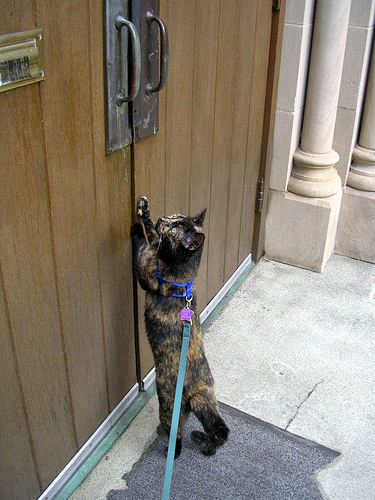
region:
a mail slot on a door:
[0, 24, 47, 99]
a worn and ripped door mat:
[96, 391, 346, 498]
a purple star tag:
[175, 299, 195, 326]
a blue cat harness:
[150, 254, 204, 303]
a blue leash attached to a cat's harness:
[153, 300, 192, 497]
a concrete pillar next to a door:
[285, 0, 356, 196]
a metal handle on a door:
[102, 0, 134, 156]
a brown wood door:
[132, 0, 276, 392]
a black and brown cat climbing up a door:
[124, 194, 233, 449]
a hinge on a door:
[252, 172, 268, 217]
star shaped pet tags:
[177, 306, 201, 325]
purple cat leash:
[159, 318, 183, 498]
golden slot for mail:
[0, 32, 45, 90]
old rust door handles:
[102, 5, 166, 146]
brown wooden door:
[64, 4, 276, 211]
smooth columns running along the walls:
[282, 7, 372, 217]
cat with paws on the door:
[123, 176, 225, 454]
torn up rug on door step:
[167, 407, 327, 493]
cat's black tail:
[192, 402, 237, 462]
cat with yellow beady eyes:
[163, 207, 180, 237]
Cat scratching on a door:
[129, 191, 231, 457]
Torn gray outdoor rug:
[103, 392, 350, 498]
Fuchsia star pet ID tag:
[177, 301, 195, 325]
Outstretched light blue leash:
[161, 317, 199, 498]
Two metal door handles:
[99, 0, 169, 154]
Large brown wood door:
[0, 0, 288, 498]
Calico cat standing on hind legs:
[128, 194, 231, 458]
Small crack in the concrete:
[279, 260, 374, 430]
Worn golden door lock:
[0, 25, 54, 97]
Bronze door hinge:
[254, 175, 265, 215]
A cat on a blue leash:
[134, 198, 230, 498]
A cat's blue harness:
[152, 262, 198, 301]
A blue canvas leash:
[160, 291, 193, 498]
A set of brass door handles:
[102, 2, 163, 154]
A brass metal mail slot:
[0, 26, 48, 92]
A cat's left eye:
[168, 223, 179, 234]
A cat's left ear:
[191, 223, 204, 250]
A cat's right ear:
[190, 204, 208, 225]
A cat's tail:
[192, 392, 228, 446]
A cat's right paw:
[136, 196, 154, 232]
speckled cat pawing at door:
[126, 194, 229, 450]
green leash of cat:
[154, 316, 201, 496]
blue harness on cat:
[152, 262, 195, 298]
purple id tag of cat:
[177, 303, 202, 324]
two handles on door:
[106, 3, 162, 140]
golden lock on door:
[6, 20, 49, 85]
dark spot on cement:
[89, 390, 347, 498]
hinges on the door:
[257, 0, 286, 219]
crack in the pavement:
[255, 303, 363, 424]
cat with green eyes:
[128, 189, 235, 456]